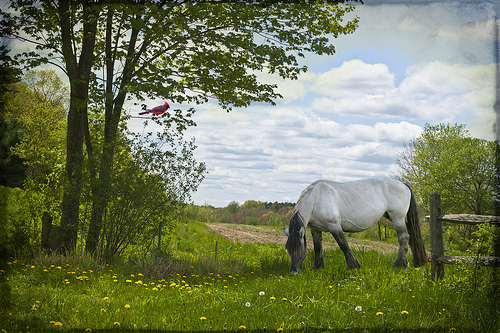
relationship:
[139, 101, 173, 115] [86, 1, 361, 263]
bird in tree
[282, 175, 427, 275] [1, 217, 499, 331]
horse in grass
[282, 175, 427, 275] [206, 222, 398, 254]
horse by road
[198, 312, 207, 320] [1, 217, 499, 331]
flower in grass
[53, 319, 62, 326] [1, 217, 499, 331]
flower in grass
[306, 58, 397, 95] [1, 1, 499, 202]
cloud in sky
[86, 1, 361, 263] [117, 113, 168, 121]
tree has branch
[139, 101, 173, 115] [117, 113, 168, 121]
bird on branch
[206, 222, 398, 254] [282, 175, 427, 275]
road behind horse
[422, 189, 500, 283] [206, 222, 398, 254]
fence beside road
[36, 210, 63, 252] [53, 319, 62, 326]
stump behind flower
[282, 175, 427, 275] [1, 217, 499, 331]
horse eating grass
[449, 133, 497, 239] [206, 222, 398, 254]
tree across road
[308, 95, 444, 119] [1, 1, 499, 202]
cloud in sky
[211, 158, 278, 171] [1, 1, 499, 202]
cloud in sky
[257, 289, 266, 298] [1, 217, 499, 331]
dandelion in grass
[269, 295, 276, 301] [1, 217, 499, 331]
dandelion in grass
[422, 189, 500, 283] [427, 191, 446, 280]
fence has post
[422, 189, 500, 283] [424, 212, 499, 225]
fence has rail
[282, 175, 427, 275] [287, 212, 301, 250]
horse has mane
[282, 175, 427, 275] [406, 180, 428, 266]
horse has tail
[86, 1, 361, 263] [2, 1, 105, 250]
tree by tree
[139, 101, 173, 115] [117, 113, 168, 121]
bird perched on branch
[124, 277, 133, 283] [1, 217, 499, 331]
dandelion in grass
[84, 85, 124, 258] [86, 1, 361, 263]
trunk of tree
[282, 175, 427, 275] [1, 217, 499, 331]
horse grazing on grass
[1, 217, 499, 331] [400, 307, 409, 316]
grass with flower